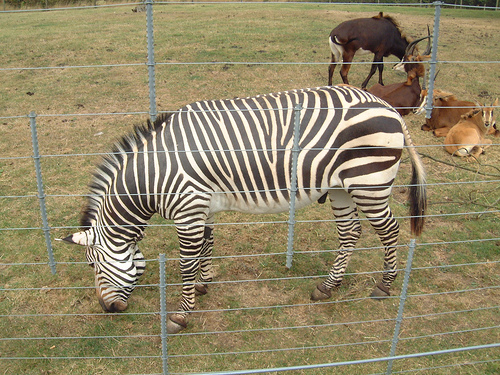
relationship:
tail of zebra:
[393, 100, 443, 242] [82, 79, 439, 279]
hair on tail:
[402, 159, 440, 242] [401, 117, 428, 235]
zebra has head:
[55, 81, 432, 334] [39, 119, 183, 323]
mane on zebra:
[76, 113, 171, 231] [66, 92, 451, 305]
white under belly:
[200, 189, 343, 229] [205, 175, 344, 213]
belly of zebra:
[205, 175, 344, 213] [55, 81, 432, 334]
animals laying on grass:
[355, 51, 489, 161] [4, 10, 488, 356]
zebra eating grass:
[62, 83, 427, 334] [10, 52, 489, 354]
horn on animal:
[405, 35, 434, 56] [314, 6, 439, 96]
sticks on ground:
[410, 140, 490, 201] [36, 51, 464, 334]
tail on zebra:
[401, 117, 428, 235] [55, 81, 432, 334]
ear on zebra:
[63, 229, 94, 247] [34, 80, 455, 343]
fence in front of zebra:
[14, 52, 486, 352] [62, 83, 427, 334]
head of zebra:
[59, 215, 150, 302] [74, 79, 428, 324]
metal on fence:
[130, 240, 194, 363] [14, 52, 486, 352]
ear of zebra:
[56, 210, 105, 264] [74, 79, 428, 324]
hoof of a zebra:
[160, 311, 187, 335] [55, 81, 432, 334]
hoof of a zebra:
[194, 270, 213, 291] [55, 81, 432, 334]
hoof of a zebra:
[310, 285, 332, 300] [55, 81, 432, 334]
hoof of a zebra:
[370, 285, 389, 300] [55, 81, 432, 334]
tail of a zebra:
[401, 117, 428, 235] [74, 79, 428, 324]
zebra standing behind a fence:
[55, 81, 432, 334] [9, 20, 485, 367]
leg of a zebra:
[165, 221, 203, 332] [55, 81, 432, 334]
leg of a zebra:
[309, 201, 366, 305] [55, 81, 432, 334]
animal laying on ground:
[444, 97, 499, 158] [10, 18, 485, 354]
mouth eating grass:
[106, 300, 125, 314] [86, 292, 145, 319]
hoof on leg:
[309, 279, 339, 305] [306, 197, 364, 302]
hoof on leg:
[368, 283, 392, 298] [352, 184, 400, 297]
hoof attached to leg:
[166, 313, 186, 334] [162, 222, 205, 336]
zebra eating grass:
[55, 81, 432, 334] [75, 263, 165, 331]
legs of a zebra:
[164, 189, 406, 329] [55, 81, 432, 334]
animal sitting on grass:
[444, 113, 484, 155] [4, 10, 488, 356]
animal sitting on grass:
[415, 85, 471, 125] [4, 10, 488, 356]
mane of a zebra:
[76, 113, 171, 231] [55, 81, 432, 334]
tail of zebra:
[401, 117, 428, 235] [55, 81, 432, 334]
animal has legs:
[319, 11, 428, 89] [326, 54, 387, 86]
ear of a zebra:
[63, 229, 94, 247] [55, 81, 432, 334]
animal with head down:
[328, 13, 432, 91] [393, 32, 435, 76]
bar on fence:
[25, 110, 60, 303] [14, 52, 486, 352]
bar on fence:
[136, 10, 164, 137] [9, 20, 485, 367]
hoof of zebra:
[310, 285, 332, 300] [55, 81, 432, 334]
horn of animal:
[406, 32, 430, 53] [319, 11, 428, 89]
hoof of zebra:
[166, 313, 186, 334] [55, 81, 432, 334]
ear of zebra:
[63, 229, 94, 247] [55, 81, 432, 334]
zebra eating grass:
[55, 81, 432, 334] [4, 10, 488, 356]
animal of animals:
[420, 94, 475, 137] [324, 10, 481, 161]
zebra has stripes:
[55, 81, 432, 334] [58, 83, 438, 312]